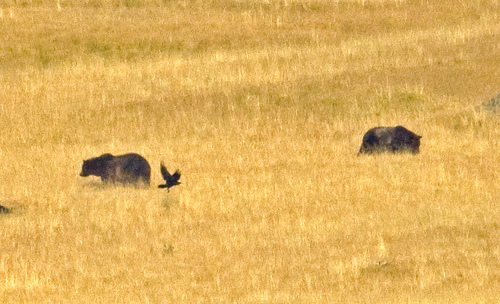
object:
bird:
[155, 159, 183, 193]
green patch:
[368, 90, 425, 115]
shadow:
[83, 181, 150, 190]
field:
[0, 0, 496, 303]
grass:
[0, 0, 498, 303]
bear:
[354, 125, 420, 156]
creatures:
[0, 204, 14, 214]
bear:
[78, 152, 150, 188]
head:
[78, 158, 95, 178]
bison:
[77, 153, 151, 189]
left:
[354, 125, 423, 158]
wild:
[0, 0, 498, 304]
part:
[0, 216, 499, 303]